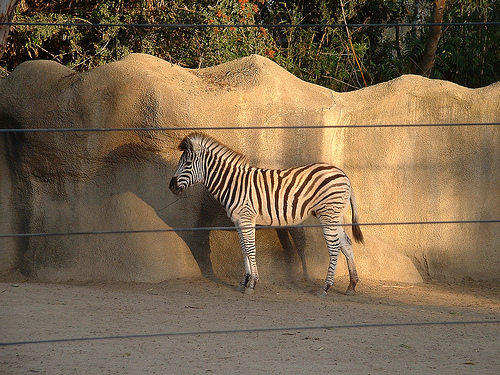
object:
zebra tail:
[349, 189, 369, 250]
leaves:
[314, 343, 331, 351]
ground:
[1, 274, 500, 373]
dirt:
[0, 280, 500, 373]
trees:
[189, 0, 297, 70]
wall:
[0, 51, 500, 285]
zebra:
[169, 129, 367, 298]